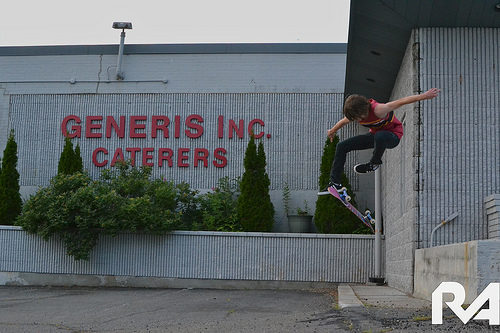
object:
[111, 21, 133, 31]
camera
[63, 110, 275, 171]
letters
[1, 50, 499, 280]
building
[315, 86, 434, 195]
guy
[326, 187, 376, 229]
skateboard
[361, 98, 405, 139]
shirt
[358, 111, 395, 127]
stripes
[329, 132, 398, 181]
jeans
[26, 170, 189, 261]
bushes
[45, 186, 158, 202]
flowers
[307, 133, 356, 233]
tree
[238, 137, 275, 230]
tree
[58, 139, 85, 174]
tree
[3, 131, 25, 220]
tree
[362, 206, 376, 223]
wheels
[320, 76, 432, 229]
trick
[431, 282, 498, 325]
ra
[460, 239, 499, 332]
corner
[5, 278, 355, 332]
pavement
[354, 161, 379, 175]
shoe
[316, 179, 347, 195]
shoe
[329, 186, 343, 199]
part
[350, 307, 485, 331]
part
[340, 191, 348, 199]
part